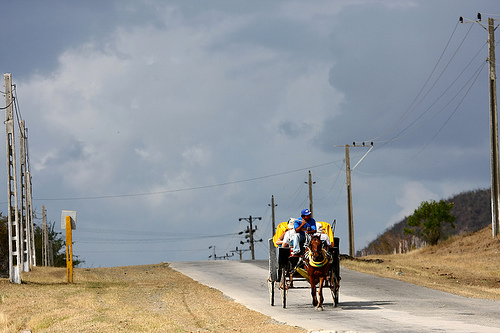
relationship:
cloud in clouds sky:
[11, 0, 500, 216] [0, 0, 500, 247]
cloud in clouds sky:
[11, 27, 330, 159] [0, 0, 500, 247]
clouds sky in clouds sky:
[174, 193, 235, 233] [0, 0, 500, 247]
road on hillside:
[166, 257, 499, 331] [358, 183, 499, 269]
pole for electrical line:
[344, 141, 354, 259] [254, 8, 483, 235]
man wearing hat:
[293, 207, 323, 241] [301, 207, 311, 217]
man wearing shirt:
[293, 207, 323, 241] [292, 216, 316, 236]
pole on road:
[339, 141, 383, 259] [166, 257, 499, 331]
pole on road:
[488, 16, 498, 237] [166, 257, 499, 331]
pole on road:
[301, 167, 317, 219] [166, 257, 499, 331]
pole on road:
[264, 189, 281, 258] [166, 257, 499, 331]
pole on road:
[236, 212, 263, 262] [166, 257, 499, 331]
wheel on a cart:
[281, 267, 288, 308] [269, 234, 344, 304]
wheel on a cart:
[277, 262, 288, 308] [269, 234, 342, 311]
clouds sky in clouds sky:
[0, 0, 500, 247] [0, 0, 500, 247]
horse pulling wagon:
[289, 228, 342, 303] [253, 218, 368, 310]